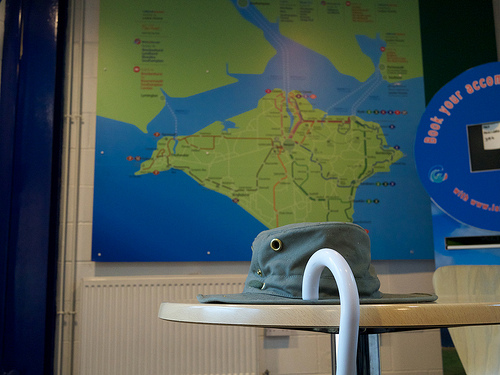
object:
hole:
[269, 238, 283, 252]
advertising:
[414, 63, 500, 231]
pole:
[301, 248, 362, 375]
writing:
[425, 69, 500, 150]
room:
[0, 0, 499, 375]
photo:
[0, 0, 499, 375]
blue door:
[0, 0, 63, 373]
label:
[301, 248, 361, 375]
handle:
[298, 247, 361, 375]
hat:
[195, 220, 438, 307]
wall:
[0, 0, 498, 372]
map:
[92, 0, 427, 266]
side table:
[154, 302, 500, 335]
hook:
[300, 245, 364, 374]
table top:
[154, 297, 500, 336]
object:
[302, 248, 362, 374]